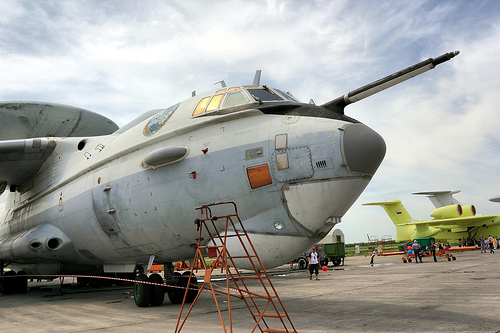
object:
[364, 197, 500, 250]
airplane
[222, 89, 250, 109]
window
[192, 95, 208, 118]
window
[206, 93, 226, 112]
window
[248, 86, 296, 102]
window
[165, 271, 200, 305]
wheels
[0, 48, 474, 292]
aircraft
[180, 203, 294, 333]
stepladder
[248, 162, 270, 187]
hatch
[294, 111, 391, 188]
nose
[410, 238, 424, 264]
people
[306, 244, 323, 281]
man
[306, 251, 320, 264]
shirt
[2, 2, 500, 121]
sky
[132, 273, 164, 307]
wheels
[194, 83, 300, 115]
cockpit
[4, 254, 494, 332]
runway